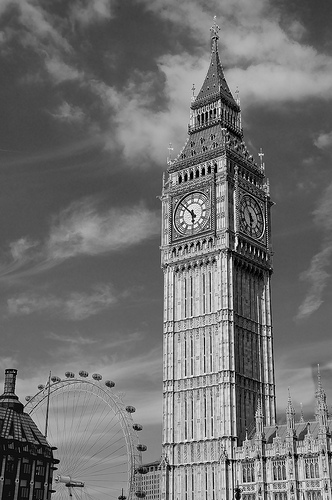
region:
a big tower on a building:
[133, 13, 300, 420]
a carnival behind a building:
[30, 362, 156, 498]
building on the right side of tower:
[240, 369, 330, 498]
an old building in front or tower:
[3, 351, 63, 498]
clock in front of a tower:
[168, 184, 213, 239]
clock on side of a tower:
[233, 186, 273, 248]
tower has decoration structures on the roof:
[157, 113, 267, 166]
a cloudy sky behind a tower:
[9, 1, 326, 409]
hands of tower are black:
[177, 199, 200, 228]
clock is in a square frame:
[159, 172, 218, 246]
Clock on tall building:
[170, 173, 222, 246]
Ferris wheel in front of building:
[19, 360, 161, 498]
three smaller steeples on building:
[237, 366, 330, 448]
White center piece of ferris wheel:
[51, 473, 81, 488]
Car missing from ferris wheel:
[115, 392, 128, 407]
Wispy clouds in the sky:
[14, 235, 169, 382]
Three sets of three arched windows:
[235, 461, 330, 483]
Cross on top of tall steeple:
[209, 14, 234, 43]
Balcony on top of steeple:
[181, 95, 241, 132]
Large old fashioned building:
[134, 133, 330, 496]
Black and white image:
[122, 24, 310, 386]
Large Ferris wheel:
[49, 369, 158, 498]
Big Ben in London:
[135, 9, 291, 317]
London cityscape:
[16, 25, 330, 485]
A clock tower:
[149, 18, 282, 357]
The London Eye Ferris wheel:
[40, 377, 160, 490]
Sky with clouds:
[33, 118, 141, 361]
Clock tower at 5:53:
[162, 185, 221, 250]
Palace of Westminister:
[235, 404, 315, 497]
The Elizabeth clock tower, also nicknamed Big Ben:
[149, 55, 282, 383]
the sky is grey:
[59, 240, 215, 403]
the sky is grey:
[77, 295, 120, 327]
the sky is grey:
[65, 257, 110, 300]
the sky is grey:
[83, 315, 183, 373]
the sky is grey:
[34, 252, 102, 306]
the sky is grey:
[97, 301, 99, 306]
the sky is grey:
[36, 245, 127, 340]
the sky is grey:
[60, 255, 69, 263]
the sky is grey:
[57, 280, 87, 310]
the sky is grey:
[74, 311, 104, 344]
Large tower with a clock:
[157, 22, 277, 497]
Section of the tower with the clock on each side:
[160, 156, 276, 271]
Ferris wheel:
[24, 360, 152, 498]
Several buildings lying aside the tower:
[231, 361, 329, 497]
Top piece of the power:
[187, 14, 249, 130]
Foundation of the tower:
[158, 247, 277, 497]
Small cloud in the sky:
[6, 186, 159, 279]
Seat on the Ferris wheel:
[107, 380, 119, 389]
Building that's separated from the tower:
[2, 363, 60, 496]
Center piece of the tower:
[64, 482, 93, 490]